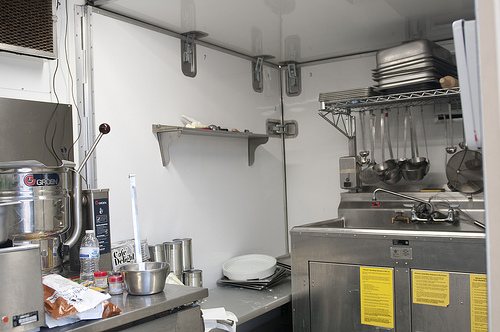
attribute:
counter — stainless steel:
[41, 275, 209, 331]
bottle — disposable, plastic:
[77, 229, 101, 285]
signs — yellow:
[358, 266, 488, 331]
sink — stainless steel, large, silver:
[286, 215, 487, 238]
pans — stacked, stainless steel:
[370, 36, 457, 92]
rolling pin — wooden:
[438, 72, 458, 94]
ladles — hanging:
[352, 100, 467, 185]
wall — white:
[0, 0, 289, 291]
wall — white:
[278, 38, 465, 258]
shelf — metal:
[150, 119, 270, 167]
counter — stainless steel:
[192, 252, 291, 331]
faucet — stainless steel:
[370, 187, 458, 222]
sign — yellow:
[357, 264, 395, 330]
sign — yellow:
[412, 268, 450, 307]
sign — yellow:
[468, 272, 485, 331]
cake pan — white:
[223, 253, 276, 283]